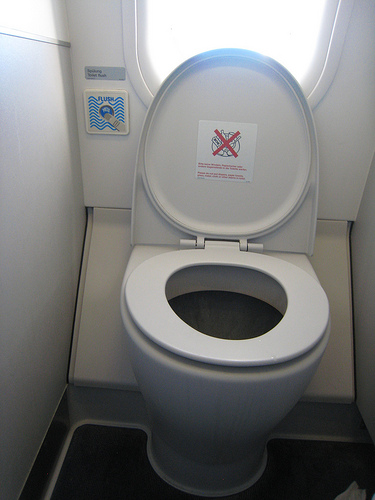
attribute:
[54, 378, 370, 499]
board — grey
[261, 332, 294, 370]
seat — round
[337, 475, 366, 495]
paper — white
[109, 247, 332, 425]
toilet — small, white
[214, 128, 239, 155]
letters — red 